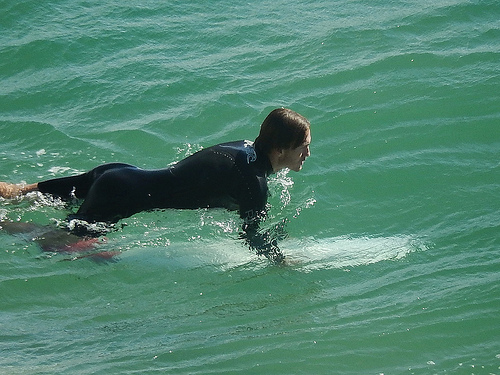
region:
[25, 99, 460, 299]
Man riding his surfboard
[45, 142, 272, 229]
Surfer's wetsuit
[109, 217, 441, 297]
Submerged surf board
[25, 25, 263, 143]
Ripples on ocean water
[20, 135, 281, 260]
Man making his way through water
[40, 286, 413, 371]
Clean looking ocean water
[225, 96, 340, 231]
Surfer looking ahead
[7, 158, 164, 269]
Surfer's legs kicking through water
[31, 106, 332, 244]
Surfer wearing a black wetsuit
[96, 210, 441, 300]
White surfboard under water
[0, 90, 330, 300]
Woman is surfing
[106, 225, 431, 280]
Surfboard under water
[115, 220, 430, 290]
Surfboard is white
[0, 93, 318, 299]
Man wears black suit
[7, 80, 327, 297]
Man swims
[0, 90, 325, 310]
Man is face down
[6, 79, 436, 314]
Man holds a surfboard that is underwater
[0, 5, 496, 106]
Water is green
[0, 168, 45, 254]
Legs of surfer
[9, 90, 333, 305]
Man is facing to the right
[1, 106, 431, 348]
A man riding a surboard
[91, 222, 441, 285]
A surfboard under water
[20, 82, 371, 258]
A man wearing a wetsuit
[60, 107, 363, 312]
A man riding a surfboard on his hands and knees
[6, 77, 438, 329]
A man riding a surfboard in the ocean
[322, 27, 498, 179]
Blue green ocean water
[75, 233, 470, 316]
A white and red surfboard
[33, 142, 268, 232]
A black wetsuit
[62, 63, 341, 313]
A man who is wet with ocean water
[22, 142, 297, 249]
Waves created by a man surfing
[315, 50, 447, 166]
Water is green color.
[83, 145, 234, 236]
One man is surfing.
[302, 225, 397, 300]
Surfing board is white color.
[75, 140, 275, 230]
Man is in black dress.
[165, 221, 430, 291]
Surfing board is inside the water.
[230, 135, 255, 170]
Design at the back of the dress.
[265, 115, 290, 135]
Hair is brown color.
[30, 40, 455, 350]
Day time picture.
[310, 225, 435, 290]
One surfing board is seen.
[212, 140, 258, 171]
Design is blue color.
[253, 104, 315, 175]
The head of a young male surfer.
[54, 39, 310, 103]
Waves in the green water.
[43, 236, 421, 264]
White surfboard under the water.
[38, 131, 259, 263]
The surfer all in black.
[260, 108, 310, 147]
The surfer's wet brown hair.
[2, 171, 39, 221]
The surfer's left leg.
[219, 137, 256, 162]
The decoration on the wet suit.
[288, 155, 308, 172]
The young surfer's mouth agape.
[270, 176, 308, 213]
The water splashing around the surfer.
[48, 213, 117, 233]
The white foam in the water.